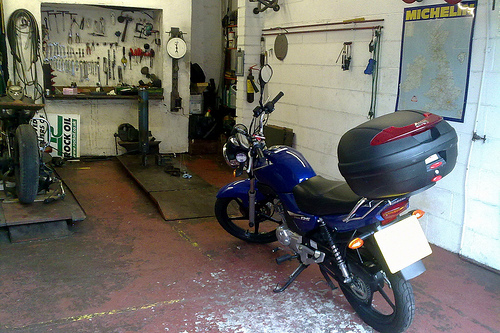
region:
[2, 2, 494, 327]
A motorcycle garage scene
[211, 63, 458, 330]
A motorcycle is inside the garage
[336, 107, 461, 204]
A cargo container is on the motorcycle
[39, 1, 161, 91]
Tools are hanging on the wall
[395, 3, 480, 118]
A sign is on the wall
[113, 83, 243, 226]
This is a motorcycle lift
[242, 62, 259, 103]
A fire exstinguisher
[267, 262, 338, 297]
The motorcycle's kickstand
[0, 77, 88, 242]
This motorcycle is on a lift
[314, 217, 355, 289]
The motorcycle's rear shock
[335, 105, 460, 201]
Black storage container on back of motorcycle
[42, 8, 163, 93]
Tools hanging on garage wall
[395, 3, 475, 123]
Michelin sign on wall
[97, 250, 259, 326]
Painted garage floor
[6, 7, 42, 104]
Wires hanging on the wall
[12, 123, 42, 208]
Black tire on rack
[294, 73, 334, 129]
White cement brick wall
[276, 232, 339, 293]
Kickstand of motorcycle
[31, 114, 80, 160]
Green and white sign leaning against wall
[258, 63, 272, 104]
Side view mirror of motorcycle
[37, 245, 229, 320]
dirty floor of a work room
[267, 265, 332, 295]
bike's kick stands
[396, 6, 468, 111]
map on the wall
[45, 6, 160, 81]
an array of tools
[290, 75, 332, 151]
wall of concrete blocks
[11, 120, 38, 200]
well worn tire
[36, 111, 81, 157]
business sign leaned against the wall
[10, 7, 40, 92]
hanging hose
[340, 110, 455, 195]
storage compartment for bike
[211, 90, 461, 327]
motorcycle in a garage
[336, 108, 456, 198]
storage space attachment for a motorcycle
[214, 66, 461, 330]
a blue motorcycle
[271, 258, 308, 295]
a black motorcycle kickstand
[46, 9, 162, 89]
tools hanging on wall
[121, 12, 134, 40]
a hammer hanging on wall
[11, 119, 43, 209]
a motorcycle tire with very little tread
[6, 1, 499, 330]
a mechanic shop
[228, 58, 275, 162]
motorcycle rearview mirrors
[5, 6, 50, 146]
hose hanging on wall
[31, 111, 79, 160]
a green and white sign that say "Rock Oil"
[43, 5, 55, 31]
tool hanging on wall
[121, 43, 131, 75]
tool hanging on wall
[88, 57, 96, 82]
tool hanging on wall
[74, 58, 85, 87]
tool hanging on wall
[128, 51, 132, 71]
tool hanging on wall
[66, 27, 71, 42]
tool hanging on wall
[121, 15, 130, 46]
tool hanging on wall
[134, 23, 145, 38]
tool hanging on wall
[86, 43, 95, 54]
tool hanging on wall